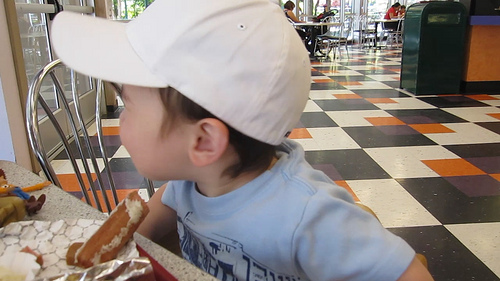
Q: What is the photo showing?
A: It is showing a restaurant.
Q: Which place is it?
A: It is a restaurant.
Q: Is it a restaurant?
A: Yes, it is a restaurant.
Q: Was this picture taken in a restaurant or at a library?
A: It was taken at a restaurant.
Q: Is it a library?
A: No, it is a restaurant.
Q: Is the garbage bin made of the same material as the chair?
A: Yes, both the garbage bin and the chair are made of metal.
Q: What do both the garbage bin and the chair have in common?
A: The material, both the garbage bin and the chair are metallic.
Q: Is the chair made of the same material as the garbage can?
A: Yes, both the chair and the garbage can are made of metal.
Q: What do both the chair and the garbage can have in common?
A: The material, both the chair and the garbage can are metallic.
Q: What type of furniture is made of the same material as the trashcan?
A: The chair is made of the same material as the trashcan.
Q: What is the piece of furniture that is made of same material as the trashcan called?
A: The piece of furniture is a chair.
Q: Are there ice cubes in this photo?
A: No, there are no ice cubes.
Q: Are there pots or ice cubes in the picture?
A: No, there are no ice cubes or pots.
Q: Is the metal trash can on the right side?
A: Yes, the garbage bin is on the right of the image.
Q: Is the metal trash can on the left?
A: No, the garbage can is on the right of the image.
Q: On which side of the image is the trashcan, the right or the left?
A: The trashcan is on the right of the image.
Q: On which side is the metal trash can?
A: The garbage can is on the right of the image.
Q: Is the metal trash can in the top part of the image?
A: Yes, the trash bin is in the top of the image.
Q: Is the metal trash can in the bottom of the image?
A: No, the trashcan is in the top of the image.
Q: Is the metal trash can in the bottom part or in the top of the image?
A: The garbage bin is in the top of the image.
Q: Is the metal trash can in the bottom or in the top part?
A: The garbage bin is in the top of the image.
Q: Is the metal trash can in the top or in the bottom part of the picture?
A: The garbage bin is in the top of the image.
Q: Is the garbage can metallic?
A: Yes, the garbage can is metallic.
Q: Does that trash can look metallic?
A: Yes, the trash can is metallic.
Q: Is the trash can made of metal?
A: Yes, the trash can is made of metal.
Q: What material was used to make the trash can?
A: The trash can is made of metal.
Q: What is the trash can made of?
A: The trash can is made of metal.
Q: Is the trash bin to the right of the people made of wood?
A: No, the trash can is made of metal.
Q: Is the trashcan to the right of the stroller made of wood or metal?
A: The garbage can is made of metal.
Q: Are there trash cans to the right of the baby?
A: Yes, there is a trash can to the right of the baby.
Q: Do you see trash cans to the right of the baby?
A: Yes, there is a trash can to the right of the baby.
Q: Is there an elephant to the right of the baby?
A: No, there is a trash can to the right of the baby.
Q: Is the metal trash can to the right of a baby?
A: Yes, the garbage can is to the right of a baby.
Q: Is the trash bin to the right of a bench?
A: No, the trash bin is to the right of a baby.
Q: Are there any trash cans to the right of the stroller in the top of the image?
A: Yes, there is a trash can to the right of the stroller.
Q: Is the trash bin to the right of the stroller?
A: Yes, the trash bin is to the right of the stroller.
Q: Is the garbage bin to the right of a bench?
A: No, the garbage bin is to the right of the stroller.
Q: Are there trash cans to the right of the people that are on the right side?
A: Yes, there is a trash can to the right of the people.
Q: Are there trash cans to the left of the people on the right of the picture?
A: No, the trash can is to the right of the people.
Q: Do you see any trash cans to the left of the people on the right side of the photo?
A: No, the trash can is to the right of the people.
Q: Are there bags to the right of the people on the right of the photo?
A: No, there is a trash can to the right of the people.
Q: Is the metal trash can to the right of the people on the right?
A: Yes, the trash can is to the right of the people.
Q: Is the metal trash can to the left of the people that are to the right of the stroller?
A: No, the garbage bin is to the right of the people.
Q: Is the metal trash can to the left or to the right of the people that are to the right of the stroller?
A: The garbage bin is to the right of the people.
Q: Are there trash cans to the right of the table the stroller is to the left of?
A: Yes, there is a trash can to the right of the table.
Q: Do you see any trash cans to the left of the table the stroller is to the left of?
A: No, the trash can is to the right of the table.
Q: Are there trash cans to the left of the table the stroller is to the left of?
A: No, the trash can is to the right of the table.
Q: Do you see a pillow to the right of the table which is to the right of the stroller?
A: No, there is a trash can to the right of the table.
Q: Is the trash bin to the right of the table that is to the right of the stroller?
A: Yes, the trash bin is to the right of the table.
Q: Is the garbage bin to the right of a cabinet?
A: No, the garbage bin is to the right of the table.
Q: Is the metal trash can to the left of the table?
A: No, the garbage can is to the right of the table.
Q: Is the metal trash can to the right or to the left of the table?
A: The garbage can is to the right of the table.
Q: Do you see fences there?
A: No, there are no fences.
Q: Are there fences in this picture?
A: No, there are no fences.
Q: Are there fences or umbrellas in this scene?
A: No, there are no fences or umbrellas.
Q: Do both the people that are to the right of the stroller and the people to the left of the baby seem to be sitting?
A: Yes, both the people and the people are sitting.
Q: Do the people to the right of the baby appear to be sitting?
A: Yes, the people are sitting.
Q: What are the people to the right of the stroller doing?
A: The people are sitting.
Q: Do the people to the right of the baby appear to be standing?
A: No, the people are sitting.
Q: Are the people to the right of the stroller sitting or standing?
A: The people are sitting.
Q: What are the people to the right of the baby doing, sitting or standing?
A: The people are sitting.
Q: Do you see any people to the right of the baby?
A: Yes, there are people to the right of the baby.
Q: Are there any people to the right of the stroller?
A: Yes, there are people to the right of the stroller.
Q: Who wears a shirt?
A: The people wear a shirt.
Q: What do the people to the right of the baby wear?
A: The people wear a shirt.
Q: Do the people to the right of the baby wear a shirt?
A: Yes, the people wear a shirt.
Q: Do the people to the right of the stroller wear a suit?
A: No, the people wear a shirt.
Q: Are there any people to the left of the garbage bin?
A: Yes, there are people to the left of the garbage bin.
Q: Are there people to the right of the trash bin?
A: No, the people are to the left of the trash bin.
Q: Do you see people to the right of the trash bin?
A: No, the people are to the left of the trash bin.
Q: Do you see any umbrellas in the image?
A: No, there are no umbrellas.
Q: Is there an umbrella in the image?
A: No, there are no umbrellas.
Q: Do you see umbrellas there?
A: No, there are no umbrellas.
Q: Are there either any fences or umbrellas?
A: No, there are no umbrellas or fences.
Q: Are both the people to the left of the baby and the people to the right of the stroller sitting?
A: Yes, both the people and the people are sitting.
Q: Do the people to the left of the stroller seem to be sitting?
A: Yes, the people are sitting.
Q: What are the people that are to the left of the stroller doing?
A: The people are sitting.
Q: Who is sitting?
A: The people are sitting.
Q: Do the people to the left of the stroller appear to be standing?
A: No, the people are sitting.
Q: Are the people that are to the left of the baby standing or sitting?
A: The people are sitting.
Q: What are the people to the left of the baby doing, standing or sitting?
A: The people are sitting.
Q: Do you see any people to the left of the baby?
A: Yes, there are people to the left of the baby.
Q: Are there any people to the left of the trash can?
A: Yes, there are people to the left of the trash can.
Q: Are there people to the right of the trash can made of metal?
A: No, the people are to the left of the garbage can.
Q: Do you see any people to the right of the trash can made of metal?
A: No, the people are to the left of the garbage can.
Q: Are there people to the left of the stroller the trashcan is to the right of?
A: Yes, there are people to the left of the stroller.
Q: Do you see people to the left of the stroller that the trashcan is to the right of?
A: Yes, there are people to the left of the stroller.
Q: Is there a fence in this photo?
A: No, there are no fences.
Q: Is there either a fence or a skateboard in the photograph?
A: No, there are no fences or skateboards.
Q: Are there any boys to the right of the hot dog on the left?
A: Yes, there is a boy to the right of the hot dog.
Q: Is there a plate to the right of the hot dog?
A: No, there is a boy to the right of the hot dog.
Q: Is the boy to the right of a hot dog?
A: Yes, the boy is to the right of a hot dog.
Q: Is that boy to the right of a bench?
A: No, the boy is to the right of a hot dog.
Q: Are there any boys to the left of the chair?
A: No, the boy is to the right of the chair.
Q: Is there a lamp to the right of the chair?
A: No, there is a boy to the right of the chair.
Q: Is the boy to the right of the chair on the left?
A: Yes, the boy is to the right of the chair.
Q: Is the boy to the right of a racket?
A: No, the boy is to the right of the chair.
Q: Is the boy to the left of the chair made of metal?
A: No, the boy is to the right of the chair.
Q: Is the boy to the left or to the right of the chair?
A: The boy is to the right of the chair.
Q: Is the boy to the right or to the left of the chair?
A: The boy is to the right of the chair.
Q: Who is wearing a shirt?
A: The boy is wearing a shirt.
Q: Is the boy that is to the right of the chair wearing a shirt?
A: Yes, the boy is wearing a shirt.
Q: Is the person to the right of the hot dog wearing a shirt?
A: Yes, the boy is wearing a shirt.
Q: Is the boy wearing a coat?
A: No, the boy is wearing a shirt.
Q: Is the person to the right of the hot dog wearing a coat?
A: No, the boy is wearing a shirt.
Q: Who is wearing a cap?
A: The boy is wearing a cap.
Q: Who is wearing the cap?
A: The boy is wearing a cap.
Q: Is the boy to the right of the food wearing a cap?
A: Yes, the boy is wearing a cap.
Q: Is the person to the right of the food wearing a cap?
A: Yes, the boy is wearing a cap.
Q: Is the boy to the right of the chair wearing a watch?
A: No, the boy is wearing a cap.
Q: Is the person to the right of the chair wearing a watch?
A: No, the boy is wearing a cap.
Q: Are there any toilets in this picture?
A: No, there are no toilets.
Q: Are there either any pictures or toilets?
A: No, there are no toilets or pictures.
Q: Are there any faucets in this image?
A: No, there are no faucets.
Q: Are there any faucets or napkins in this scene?
A: No, there are no faucets or napkins.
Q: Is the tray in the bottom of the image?
A: Yes, the tray is in the bottom of the image.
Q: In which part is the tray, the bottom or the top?
A: The tray is in the bottom of the image.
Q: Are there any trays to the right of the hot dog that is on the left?
A: Yes, there is a tray to the right of the hot dog.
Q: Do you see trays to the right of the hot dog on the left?
A: Yes, there is a tray to the right of the hot dog.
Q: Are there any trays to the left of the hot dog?
A: No, the tray is to the right of the hot dog.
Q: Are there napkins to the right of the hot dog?
A: No, there is a tray to the right of the hot dog.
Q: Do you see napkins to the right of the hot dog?
A: No, there is a tray to the right of the hot dog.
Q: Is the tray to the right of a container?
A: No, the tray is to the right of the hot dog.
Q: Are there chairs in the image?
A: Yes, there is a chair.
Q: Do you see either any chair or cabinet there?
A: Yes, there is a chair.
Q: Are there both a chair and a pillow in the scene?
A: No, there is a chair but no pillows.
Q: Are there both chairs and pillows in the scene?
A: No, there is a chair but no pillows.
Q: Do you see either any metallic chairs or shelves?
A: Yes, there is a metal chair.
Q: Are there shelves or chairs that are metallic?
A: Yes, the chair is metallic.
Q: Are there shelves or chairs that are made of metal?
A: Yes, the chair is made of metal.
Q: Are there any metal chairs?
A: Yes, there is a metal chair.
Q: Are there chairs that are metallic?
A: Yes, there is a chair that is metallic.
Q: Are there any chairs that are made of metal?
A: Yes, there is a chair that is made of metal.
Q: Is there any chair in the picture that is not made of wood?
A: Yes, there is a chair that is made of metal.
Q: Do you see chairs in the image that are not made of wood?
A: Yes, there is a chair that is made of metal.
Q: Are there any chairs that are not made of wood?
A: Yes, there is a chair that is made of metal.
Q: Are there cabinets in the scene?
A: No, there are no cabinets.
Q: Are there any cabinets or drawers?
A: No, there are no cabinets or drawers.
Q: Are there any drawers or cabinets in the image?
A: No, there are no cabinets or drawers.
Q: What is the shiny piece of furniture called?
A: The piece of furniture is a chair.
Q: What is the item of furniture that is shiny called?
A: The piece of furniture is a chair.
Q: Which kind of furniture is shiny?
A: The furniture is a chair.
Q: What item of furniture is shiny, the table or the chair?
A: The chair is shiny.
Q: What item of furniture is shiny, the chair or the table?
A: The chair is shiny.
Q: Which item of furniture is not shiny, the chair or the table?
A: The table is not shiny.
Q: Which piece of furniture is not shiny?
A: The piece of furniture is a table.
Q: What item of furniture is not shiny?
A: The piece of furniture is a table.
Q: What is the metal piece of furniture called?
A: The piece of furniture is a chair.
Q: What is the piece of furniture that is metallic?
A: The piece of furniture is a chair.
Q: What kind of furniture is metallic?
A: The furniture is a chair.